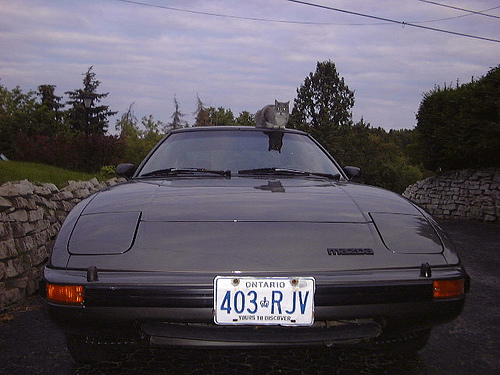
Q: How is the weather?
A: It is cloudy.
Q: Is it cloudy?
A: Yes, it is cloudy.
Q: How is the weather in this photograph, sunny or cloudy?
A: It is cloudy.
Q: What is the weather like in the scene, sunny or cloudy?
A: It is cloudy.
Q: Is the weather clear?
A: No, it is cloudy.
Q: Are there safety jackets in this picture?
A: No, there are no safety jackets.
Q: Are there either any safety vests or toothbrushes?
A: No, there are no safety vests or toothbrushes.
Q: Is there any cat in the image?
A: Yes, there is a cat.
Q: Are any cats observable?
A: Yes, there is a cat.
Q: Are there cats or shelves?
A: Yes, there is a cat.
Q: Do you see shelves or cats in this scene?
A: Yes, there is a cat.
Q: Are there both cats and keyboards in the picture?
A: No, there is a cat but no keyboards.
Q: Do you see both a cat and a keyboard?
A: No, there is a cat but no keyboards.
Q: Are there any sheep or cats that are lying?
A: Yes, the cat is lying.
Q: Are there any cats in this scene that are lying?
A: Yes, there is a cat that is lying.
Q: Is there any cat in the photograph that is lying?
A: Yes, there is a cat that is lying.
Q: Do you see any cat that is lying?
A: Yes, there is a cat that is lying.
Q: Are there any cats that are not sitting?
A: Yes, there is a cat that is lying.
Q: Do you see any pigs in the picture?
A: No, there are no pigs.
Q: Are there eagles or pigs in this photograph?
A: No, there are no pigs or eagles.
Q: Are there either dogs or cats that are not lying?
A: No, there is a cat but it is lying.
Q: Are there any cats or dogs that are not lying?
A: No, there is a cat but it is lying.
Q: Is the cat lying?
A: Yes, the cat is lying.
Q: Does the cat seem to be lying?
A: Yes, the cat is lying.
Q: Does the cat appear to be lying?
A: Yes, the cat is lying.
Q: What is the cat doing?
A: The cat is lying.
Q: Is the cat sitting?
A: No, the cat is lying.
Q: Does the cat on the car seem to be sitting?
A: No, the cat is lying.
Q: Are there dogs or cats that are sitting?
A: No, there is a cat but it is lying.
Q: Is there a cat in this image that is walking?
A: No, there is a cat but it is lying.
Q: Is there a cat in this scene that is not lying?
A: No, there is a cat but it is lying.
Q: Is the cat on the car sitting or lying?
A: The cat is lying.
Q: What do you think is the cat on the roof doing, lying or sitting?
A: The cat is lying.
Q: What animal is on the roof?
A: The cat is on the roof.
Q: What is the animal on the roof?
A: The animal is a cat.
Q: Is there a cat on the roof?
A: Yes, there is a cat on the roof.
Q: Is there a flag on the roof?
A: No, there is a cat on the roof.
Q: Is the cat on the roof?
A: Yes, the cat is on the roof.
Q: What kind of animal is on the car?
A: The animal is a cat.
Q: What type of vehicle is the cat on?
A: The cat is on the car.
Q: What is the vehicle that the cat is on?
A: The vehicle is a car.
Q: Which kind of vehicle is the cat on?
A: The cat is on the car.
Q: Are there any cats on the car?
A: Yes, there is a cat on the car.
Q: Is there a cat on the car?
A: Yes, there is a cat on the car.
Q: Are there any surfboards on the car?
A: No, there is a cat on the car.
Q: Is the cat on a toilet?
A: No, the cat is on the car.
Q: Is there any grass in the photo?
A: Yes, there is grass.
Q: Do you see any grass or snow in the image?
A: Yes, there is grass.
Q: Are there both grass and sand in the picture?
A: No, there is grass but no sand.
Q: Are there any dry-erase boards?
A: No, there are no dry-erase boards.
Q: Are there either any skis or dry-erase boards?
A: No, there are no dry-erase boards or skis.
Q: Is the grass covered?
A: Yes, the grass is covered.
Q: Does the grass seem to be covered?
A: Yes, the grass is covered.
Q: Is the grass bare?
A: No, the grass is covered.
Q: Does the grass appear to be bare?
A: No, the grass is covered.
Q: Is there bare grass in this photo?
A: No, there is grass but it is covered.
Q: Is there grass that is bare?
A: No, there is grass but it is covered.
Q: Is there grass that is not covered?
A: No, there is grass but it is covered.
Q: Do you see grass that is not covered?
A: No, there is grass but it is covered.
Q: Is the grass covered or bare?
A: The grass is covered.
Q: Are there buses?
A: No, there are no buses.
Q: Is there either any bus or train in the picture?
A: No, there are no buses or trains.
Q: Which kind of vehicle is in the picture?
A: The vehicle is a car.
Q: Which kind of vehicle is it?
A: The vehicle is a car.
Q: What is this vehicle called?
A: This is a car.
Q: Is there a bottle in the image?
A: No, there are no bottles.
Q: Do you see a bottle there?
A: No, there are no bottles.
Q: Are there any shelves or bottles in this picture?
A: No, there are no bottles or shelves.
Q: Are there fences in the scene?
A: No, there are no fences.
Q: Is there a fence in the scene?
A: No, there are no fences.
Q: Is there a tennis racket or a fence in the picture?
A: No, there are no fences or rackets.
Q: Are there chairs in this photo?
A: No, there are no chairs.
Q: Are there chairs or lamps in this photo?
A: No, there are no chairs or lamps.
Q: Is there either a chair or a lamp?
A: No, there are no chairs or lamps.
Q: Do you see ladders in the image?
A: No, there are no ladders.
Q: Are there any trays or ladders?
A: No, there are no ladders or trays.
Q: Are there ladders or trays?
A: No, there are no ladders or trays.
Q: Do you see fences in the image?
A: No, there are no fences.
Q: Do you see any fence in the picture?
A: No, there are no fences.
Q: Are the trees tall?
A: Yes, the trees are tall.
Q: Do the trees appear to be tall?
A: Yes, the trees are tall.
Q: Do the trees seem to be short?
A: No, the trees are tall.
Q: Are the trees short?
A: No, the trees are tall.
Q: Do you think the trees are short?
A: No, the trees are tall.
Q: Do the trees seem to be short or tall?
A: The trees are tall.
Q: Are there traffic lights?
A: Yes, there is a traffic light.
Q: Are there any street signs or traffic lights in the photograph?
A: Yes, there is a traffic light.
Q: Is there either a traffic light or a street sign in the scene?
A: Yes, there is a traffic light.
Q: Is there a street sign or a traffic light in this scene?
A: Yes, there is a traffic light.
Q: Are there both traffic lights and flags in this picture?
A: No, there is a traffic light but no flags.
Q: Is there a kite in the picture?
A: No, there are no kites.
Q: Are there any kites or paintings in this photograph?
A: No, there are no kites or paintings.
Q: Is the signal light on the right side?
A: Yes, the signal light is on the right of the image.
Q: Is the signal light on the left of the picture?
A: No, the signal light is on the right of the image.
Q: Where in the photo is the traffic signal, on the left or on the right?
A: The traffic signal is on the right of the image.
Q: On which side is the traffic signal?
A: The traffic signal is on the right of the image.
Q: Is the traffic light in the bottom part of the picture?
A: Yes, the traffic light is in the bottom of the image.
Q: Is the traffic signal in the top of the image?
A: No, the traffic signal is in the bottom of the image.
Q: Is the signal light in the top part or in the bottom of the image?
A: The signal light is in the bottom of the image.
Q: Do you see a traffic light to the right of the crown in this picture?
A: Yes, there is a traffic light to the right of the crown.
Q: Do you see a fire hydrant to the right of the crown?
A: No, there is a traffic light to the right of the crown.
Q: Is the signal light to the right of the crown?
A: Yes, the signal light is to the right of the crown.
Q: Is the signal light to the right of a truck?
A: No, the signal light is to the right of the crown.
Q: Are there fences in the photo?
A: No, there are no fences.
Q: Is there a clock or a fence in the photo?
A: No, there are no fences or clocks.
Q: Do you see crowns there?
A: Yes, there is a crown.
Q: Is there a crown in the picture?
A: Yes, there is a crown.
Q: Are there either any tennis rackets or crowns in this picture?
A: Yes, there is a crown.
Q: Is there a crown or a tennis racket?
A: Yes, there is a crown.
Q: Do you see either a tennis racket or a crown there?
A: Yes, there is a crown.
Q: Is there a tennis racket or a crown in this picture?
A: Yes, there is a crown.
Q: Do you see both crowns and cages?
A: No, there is a crown but no cages.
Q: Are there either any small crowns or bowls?
A: Yes, there is a small crown.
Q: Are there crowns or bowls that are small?
A: Yes, the crown is small.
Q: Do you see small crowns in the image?
A: Yes, there is a small crown.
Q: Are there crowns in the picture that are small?
A: Yes, there is a crown that is small.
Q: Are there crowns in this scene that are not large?
A: Yes, there is a small crown.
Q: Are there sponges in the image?
A: No, there are no sponges.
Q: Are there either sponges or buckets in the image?
A: No, there are no sponges or buckets.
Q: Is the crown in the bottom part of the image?
A: Yes, the crown is in the bottom of the image.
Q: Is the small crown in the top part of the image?
A: No, the crown is in the bottom of the image.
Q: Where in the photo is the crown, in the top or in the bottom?
A: The crown is in the bottom of the image.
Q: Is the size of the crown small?
A: Yes, the crown is small.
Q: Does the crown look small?
A: Yes, the crown is small.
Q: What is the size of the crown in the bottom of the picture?
A: The crown is small.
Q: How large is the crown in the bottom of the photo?
A: The crown is small.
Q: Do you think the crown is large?
A: No, the crown is small.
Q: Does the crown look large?
A: No, the crown is small.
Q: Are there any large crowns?
A: No, there is a crown but it is small.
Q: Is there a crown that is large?
A: No, there is a crown but it is small.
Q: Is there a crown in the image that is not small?
A: No, there is a crown but it is small.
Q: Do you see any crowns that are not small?
A: No, there is a crown but it is small.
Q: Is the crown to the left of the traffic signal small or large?
A: The crown is small.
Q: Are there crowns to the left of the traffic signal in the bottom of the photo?
A: Yes, there is a crown to the left of the signal light.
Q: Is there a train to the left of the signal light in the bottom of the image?
A: No, there is a crown to the left of the traffic light.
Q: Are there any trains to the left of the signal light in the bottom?
A: No, there is a crown to the left of the traffic light.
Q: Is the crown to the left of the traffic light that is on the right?
A: Yes, the crown is to the left of the traffic signal.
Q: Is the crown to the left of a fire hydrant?
A: No, the crown is to the left of the traffic signal.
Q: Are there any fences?
A: No, there are no fences.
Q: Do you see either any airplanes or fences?
A: No, there are no fences or airplanes.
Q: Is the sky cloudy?
A: Yes, the sky is cloudy.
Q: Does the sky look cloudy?
A: Yes, the sky is cloudy.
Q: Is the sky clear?
A: No, the sky is cloudy.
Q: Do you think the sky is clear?
A: No, the sky is cloudy.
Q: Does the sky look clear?
A: No, the sky is cloudy.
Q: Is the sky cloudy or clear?
A: The sky is cloudy.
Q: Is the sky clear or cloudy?
A: The sky is cloudy.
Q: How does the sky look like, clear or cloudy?
A: The sky is cloudy.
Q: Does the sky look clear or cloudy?
A: The sky is cloudy.